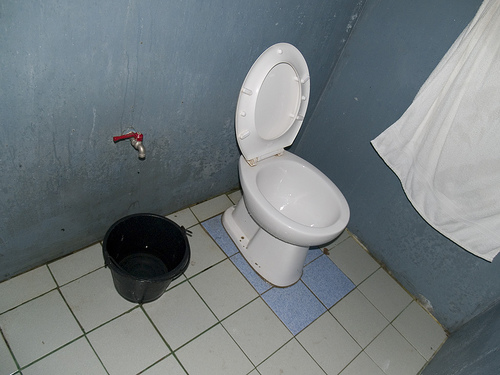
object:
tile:
[0, 264, 61, 313]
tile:
[3, 285, 93, 368]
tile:
[18, 332, 345, 354]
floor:
[4, 190, 444, 370]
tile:
[60, 301, 81, 308]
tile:
[57, 264, 139, 333]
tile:
[140, 277, 216, 353]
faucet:
[111, 125, 151, 166]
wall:
[285, 3, 495, 337]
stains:
[24, 121, 39, 137]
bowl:
[214, 35, 355, 289]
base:
[217, 191, 314, 301]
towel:
[365, 0, 498, 269]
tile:
[184, 254, 263, 324]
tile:
[216, 292, 297, 367]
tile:
[296, 314, 363, 374]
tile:
[383, 294, 456, 368]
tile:
[295, 306, 415, 322]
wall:
[2, 0, 363, 286]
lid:
[228, 40, 314, 169]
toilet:
[215, 36, 353, 291]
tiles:
[323, 284, 396, 353]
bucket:
[95, 207, 198, 311]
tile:
[292, 252, 363, 313]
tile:
[257, 274, 330, 335]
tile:
[141, 281, 225, 345]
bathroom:
[5, 1, 494, 373]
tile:
[170, 327, 260, 373]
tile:
[80, 297, 371, 327]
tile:
[199, 206, 241, 259]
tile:
[389, 295, 457, 360]